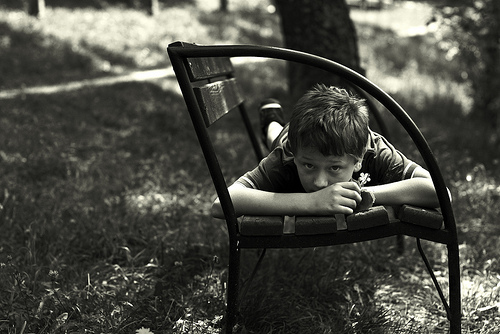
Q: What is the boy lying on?
A: A bench.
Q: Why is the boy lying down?
A: He is resting.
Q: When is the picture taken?
A: During the day.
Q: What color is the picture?
A: Black and white.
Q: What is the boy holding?
A: A flower.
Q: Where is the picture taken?
A: In the park.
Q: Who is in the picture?
A: A boy.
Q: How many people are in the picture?
A: One.